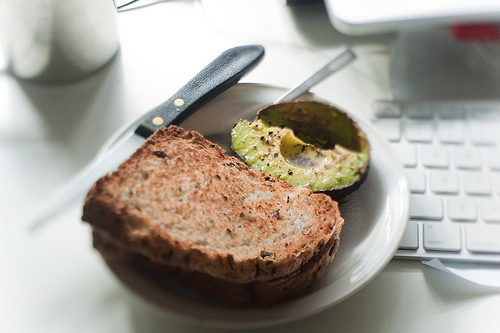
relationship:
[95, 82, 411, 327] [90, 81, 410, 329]
toast on plate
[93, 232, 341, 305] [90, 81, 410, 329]
toast on plate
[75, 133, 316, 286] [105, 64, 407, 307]
two pieces on plate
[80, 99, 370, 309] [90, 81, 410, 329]
food on plate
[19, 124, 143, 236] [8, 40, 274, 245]
blade on knife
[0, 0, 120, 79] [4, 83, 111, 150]
salt shaker on table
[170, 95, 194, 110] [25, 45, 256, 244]
bolt on knife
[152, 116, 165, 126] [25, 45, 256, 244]
bolt on knife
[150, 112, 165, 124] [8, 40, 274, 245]
bolt on knife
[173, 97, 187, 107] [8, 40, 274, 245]
bolt on knife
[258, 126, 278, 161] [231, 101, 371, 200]
spices on avocado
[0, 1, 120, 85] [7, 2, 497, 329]
mug on table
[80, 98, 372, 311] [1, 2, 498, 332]
food on desk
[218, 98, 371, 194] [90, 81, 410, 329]
avocado on plate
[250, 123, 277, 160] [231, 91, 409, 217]
pepper on avocado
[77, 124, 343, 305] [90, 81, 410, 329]
bread on plate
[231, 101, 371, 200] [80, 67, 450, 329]
avocado on plate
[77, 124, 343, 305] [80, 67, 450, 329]
bread on plate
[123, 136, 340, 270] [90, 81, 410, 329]
bread on plate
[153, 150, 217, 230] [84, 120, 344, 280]
seasoning on bread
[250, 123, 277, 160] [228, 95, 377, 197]
pepper on avocado